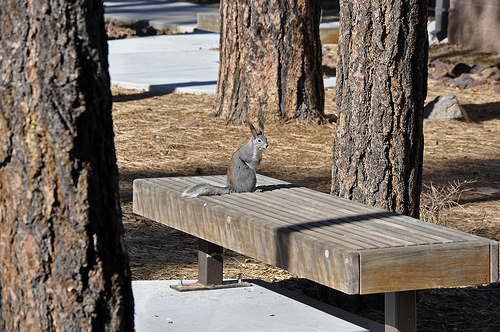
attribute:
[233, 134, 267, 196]
squirrel — gray, grey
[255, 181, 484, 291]
bench — wood, wooden, brown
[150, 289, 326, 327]
sidewalk — grey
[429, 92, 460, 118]
rock — small, gray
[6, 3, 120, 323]
tree — foreground 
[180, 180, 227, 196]
tail — gray, long, grey, furry, soft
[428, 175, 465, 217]
weed — brown, dry, dead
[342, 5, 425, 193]
trunk — brown, large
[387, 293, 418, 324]
support — wooden, metal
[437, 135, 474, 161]
material — brown, dry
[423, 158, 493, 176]
shadow — black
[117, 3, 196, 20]
drive — concrete